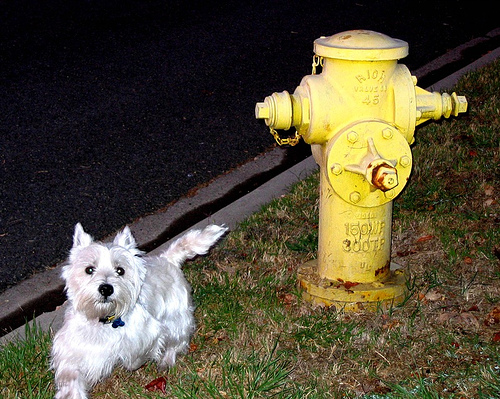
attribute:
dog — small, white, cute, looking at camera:
[48, 221, 229, 398]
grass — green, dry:
[0, 54, 499, 397]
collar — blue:
[97, 313, 117, 326]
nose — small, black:
[99, 284, 115, 297]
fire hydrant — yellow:
[255, 29, 467, 315]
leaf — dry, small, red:
[146, 377, 167, 393]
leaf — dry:
[425, 290, 444, 303]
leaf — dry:
[490, 306, 500, 325]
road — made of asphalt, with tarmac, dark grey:
[0, 0, 499, 292]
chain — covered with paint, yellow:
[269, 128, 302, 146]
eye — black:
[86, 266, 94, 274]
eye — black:
[116, 267, 126, 277]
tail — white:
[161, 225, 229, 268]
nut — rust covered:
[372, 166, 399, 193]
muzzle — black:
[83, 274, 125, 319]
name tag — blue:
[111, 315, 125, 328]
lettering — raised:
[343, 221, 387, 255]